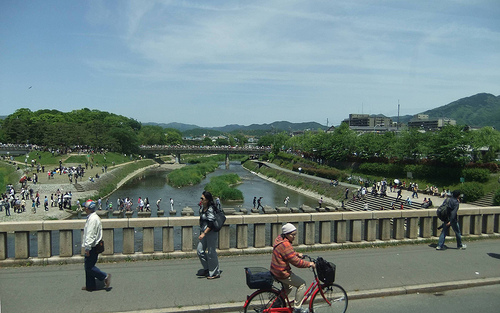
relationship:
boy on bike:
[274, 222, 313, 302] [243, 259, 350, 313]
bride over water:
[0, 219, 499, 307] [109, 161, 312, 212]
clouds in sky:
[141, 26, 305, 77] [2, 1, 500, 98]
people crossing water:
[88, 195, 200, 213] [109, 161, 312, 212]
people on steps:
[352, 177, 399, 198] [349, 187, 422, 215]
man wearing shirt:
[80, 199, 112, 292] [84, 214, 105, 249]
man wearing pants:
[80, 199, 112, 292] [84, 244, 109, 294]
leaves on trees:
[32, 120, 68, 135] [3, 105, 145, 157]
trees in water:
[172, 156, 238, 206] [109, 161, 312, 212]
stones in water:
[100, 210, 193, 218] [109, 161, 312, 212]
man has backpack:
[437, 191, 468, 250] [435, 201, 456, 224]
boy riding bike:
[274, 222, 313, 302] [243, 259, 350, 313]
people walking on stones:
[88, 195, 200, 213] [100, 210, 193, 218]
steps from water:
[349, 187, 422, 215] [109, 161, 312, 212]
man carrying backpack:
[80, 199, 112, 292] [435, 201, 456, 224]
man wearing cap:
[80, 199, 112, 292] [84, 199, 97, 210]